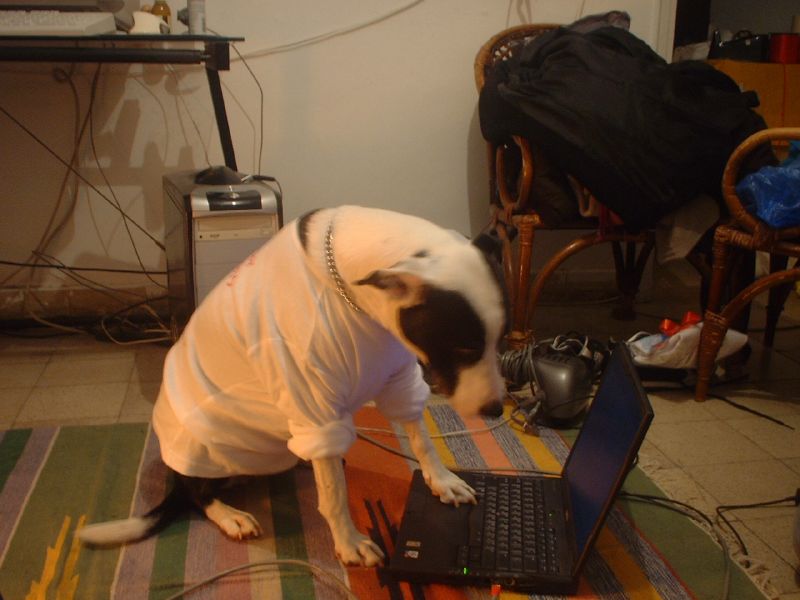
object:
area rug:
[2, 392, 770, 599]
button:
[457, 555, 473, 569]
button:
[494, 539, 508, 560]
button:
[482, 546, 524, 557]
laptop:
[383, 356, 666, 591]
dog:
[149, 197, 519, 547]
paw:
[420, 468, 484, 506]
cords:
[629, 492, 716, 533]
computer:
[399, 340, 658, 593]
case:
[166, 164, 286, 268]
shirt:
[176, 298, 374, 453]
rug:
[50, 445, 112, 504]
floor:
[46, 369, 113, 419]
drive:
[170, 164, 293, 254]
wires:
[46, 199, 147, 335]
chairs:
[468, 7, 779, 375]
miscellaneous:
[471, 11, 772, 226]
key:
[506, 480, 525, 494]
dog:
[162, 136, 498, 461]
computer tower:
[160, 162, 287, 342]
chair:
[466, 14, 762, 388]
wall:
[285, 17, 464, 206]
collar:
[298, 189, 396, 349]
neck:
[270, 206, 400, 362]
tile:
[495, 450, 691, 567]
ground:
[0, 416, 464, 599]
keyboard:
[397, 459, 583, 581]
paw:
[216, 500, 271, 547]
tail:
[70, 459, 212, 561]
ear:
[349, 269, 436, 309]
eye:
[438, 328, 478, 355]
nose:
[464, 385, 517, 426]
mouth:
[418, 363, 508, 428]